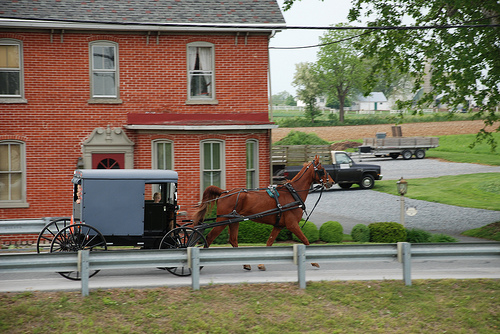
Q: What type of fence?
A: Guard rail.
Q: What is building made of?
A: Brick.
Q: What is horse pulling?
A: Buggy.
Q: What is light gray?
A: Buggy.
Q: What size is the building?
A: Large.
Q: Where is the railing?
A: Next to road.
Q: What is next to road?
A: Patch of grass.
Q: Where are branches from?
A: Tree.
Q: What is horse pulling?
A: Cart.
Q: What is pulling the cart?
A: Horse.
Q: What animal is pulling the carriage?
A: Horse.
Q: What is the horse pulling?
A: Carriage.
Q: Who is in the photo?
A: No body.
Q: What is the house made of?
A: Brick.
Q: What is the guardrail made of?
A: Metal.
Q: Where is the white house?
A: Background.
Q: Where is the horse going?
A: Down the road.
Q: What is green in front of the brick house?
A: Hedges.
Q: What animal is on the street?
A: Horse.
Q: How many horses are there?
A: One.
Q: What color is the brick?
A: Red.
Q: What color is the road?
A: Gray.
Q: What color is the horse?
A: Brown.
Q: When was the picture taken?
A: Daytime.